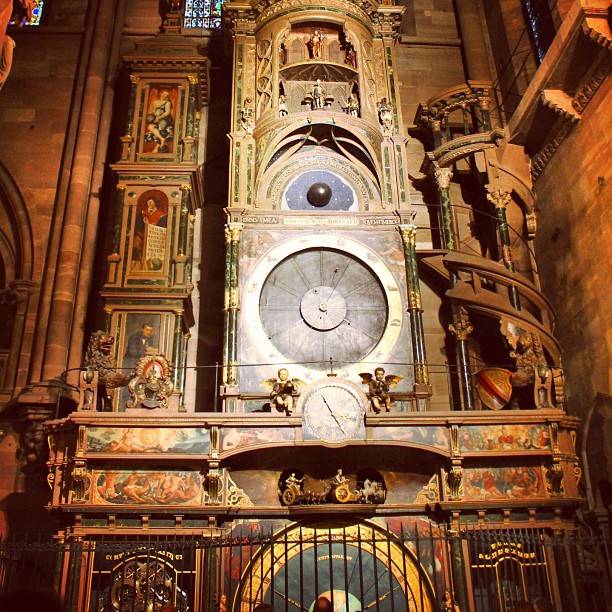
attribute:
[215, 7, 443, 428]
tower — clock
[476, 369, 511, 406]
sash — red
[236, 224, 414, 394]
clock — very old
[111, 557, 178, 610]
machine — round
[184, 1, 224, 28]
window — blue, stained-glass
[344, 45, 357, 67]
figurine — small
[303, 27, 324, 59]
figurine — small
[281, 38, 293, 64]
figurine — small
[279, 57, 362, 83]
shelf — high